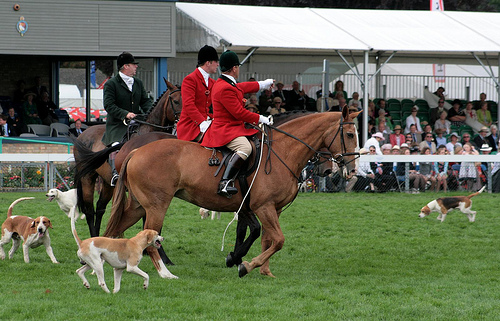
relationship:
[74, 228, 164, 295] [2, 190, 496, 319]
dog on grass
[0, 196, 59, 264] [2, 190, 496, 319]
dog on grass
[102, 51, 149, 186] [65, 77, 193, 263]
man on horse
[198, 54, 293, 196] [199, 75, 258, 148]
man wearing coats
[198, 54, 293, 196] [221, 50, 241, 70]
man wearing hat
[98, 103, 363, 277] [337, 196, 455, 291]
brown horse on grass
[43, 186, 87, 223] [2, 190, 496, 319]
dog on grass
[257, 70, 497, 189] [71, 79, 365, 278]
people watching horses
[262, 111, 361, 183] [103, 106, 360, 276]
reins on horse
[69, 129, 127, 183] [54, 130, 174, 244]
tail on horse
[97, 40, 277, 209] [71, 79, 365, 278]
people on horses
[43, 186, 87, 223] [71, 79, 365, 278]
dog behind horses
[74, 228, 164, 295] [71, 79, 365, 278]
dog behind horses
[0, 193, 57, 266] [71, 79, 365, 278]
dog behind horses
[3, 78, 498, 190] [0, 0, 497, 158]
spectators in background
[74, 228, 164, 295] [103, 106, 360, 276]
dog running around horse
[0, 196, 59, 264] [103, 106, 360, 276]
dog running around horse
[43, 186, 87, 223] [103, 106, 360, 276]
dog running around horse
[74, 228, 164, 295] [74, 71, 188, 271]
dog running around horse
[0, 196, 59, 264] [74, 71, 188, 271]
dog running around horse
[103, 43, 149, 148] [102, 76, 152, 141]
man wearing coat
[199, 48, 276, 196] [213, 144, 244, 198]
man wearing boot